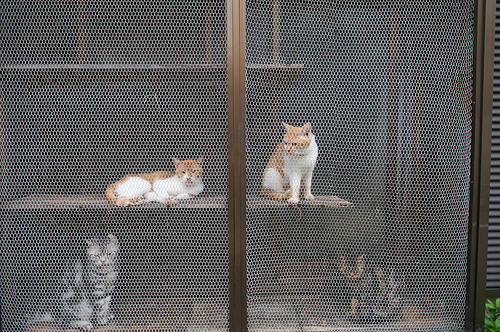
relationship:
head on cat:
[284, 114, 334, 157] [255, 117, 331, 227]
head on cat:
[329, 250, 369, 277] [321, 240, 405, 326]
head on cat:
[165, 152, 205, 184] [111, 141, 214, 205]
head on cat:
[88, 230, 121, 271] [36, 222, 145, 331]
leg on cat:
[124, 188, 166, 209] [103, 136, 217, 220]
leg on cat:
[276, 155, 298, 216] [247, 109, 317, 206]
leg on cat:
[293, 160, 311, 200] [252, 128, 317, 211]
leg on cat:
[98, 284, 115, 315] [310, 245, 410, 331]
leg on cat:
[92, 282, 129, 323] [61, 231, 115, 326]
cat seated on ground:
[54, 234, 124, 332] [102, 247, 460, 332]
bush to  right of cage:
[456, 322, 498, 332] [214, 206, 497, 332]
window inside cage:
[28, 104, 226, 203] [96, 50, 414, 255]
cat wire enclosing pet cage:
[104, 156, 205, 207] [49, 125, 439, 332]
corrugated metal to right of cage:
[434, 167, 498, 257] [405, 188, 498, 233]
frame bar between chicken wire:
[217, 57, 256, 318] [244, 261, 426, 332]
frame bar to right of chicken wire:
[439, 159, 494, 332] [412, 200, 495, 332]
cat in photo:
[11, 233, 123, 331] [48, 126, 405, 332]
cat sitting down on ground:
[11, 233, 123, 331] [117, 259, 351, 332]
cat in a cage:
[11, 233, 123, 331] [63, 104, 396, 324]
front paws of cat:
[284, 174, 314, 204] [261, 119, 330, 305]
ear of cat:
[297, 116, 337, 174] [281, 116, 327, 221]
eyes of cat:
[276, 130, 306, 160] [252, 124, 334, 261]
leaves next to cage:
[454, 318, 495, 332] [369, 306, 496, 332]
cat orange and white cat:
[104, 156, 205, 207] [94, 107, 346, 244]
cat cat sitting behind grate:
[266, 119, 322, 216] [60, 116, 464, 196]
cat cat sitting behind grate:
[110, 150, 219, 229] [15, 50, 419, 130]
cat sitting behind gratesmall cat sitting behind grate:
[11, 233, 123, 331] [2, 161, 455, 261]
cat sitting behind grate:
[330, 245, 415, 332] [263, 189, 473, 249]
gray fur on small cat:
[67, 283, 88, 332] [60, 241, 126, 322]